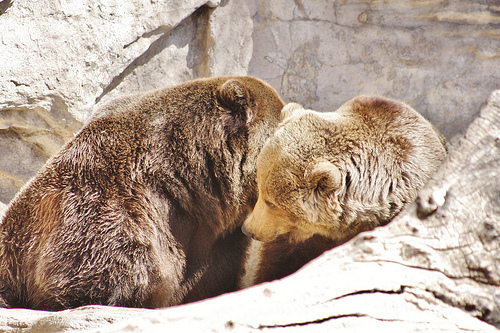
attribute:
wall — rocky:
[7, 5, 497, 201]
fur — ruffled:
[303, 95, 443, 235]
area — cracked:
[359, 231, 499, 285]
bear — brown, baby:
[231, 88, 443, 258]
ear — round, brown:
[303, 161, 342, 193]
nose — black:
[237, 217, 281, 244]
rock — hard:
[2, 2, 498, 192]